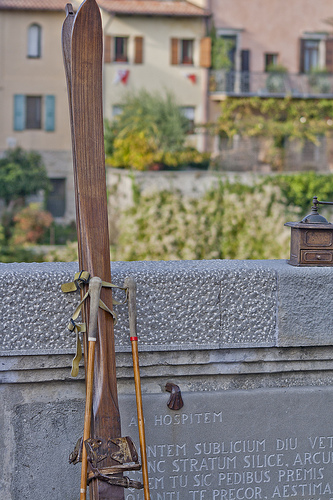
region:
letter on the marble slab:
[211, 409, 224, 426]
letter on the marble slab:
[202, 409, 212, 426]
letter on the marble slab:
[181, 412, 187, 424]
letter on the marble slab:
[154, 414, 160, 429]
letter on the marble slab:
[176, 441, 189, 458]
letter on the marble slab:
[193, 440, 202, 454]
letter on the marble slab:
[203, 442, 210, 455]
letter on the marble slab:
[210, 439, 219, 456]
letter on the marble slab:
[232, 438, 244, 453]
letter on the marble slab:
[255, 436, 270, 454]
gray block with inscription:
[5, 262, 330, 497]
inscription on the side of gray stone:
[111, 411, 331, 493]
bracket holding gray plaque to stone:
[157, 386, 184, 409]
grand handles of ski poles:
[87, 278, 135, 332]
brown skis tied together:
[54, 6, 131, 490]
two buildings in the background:
[2, 6, 332, 168]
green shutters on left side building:
[8, 92, 54, 131]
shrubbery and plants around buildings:
[2, 100, 319, 256]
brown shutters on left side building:
[104, 30, 212, 68]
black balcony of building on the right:
[212, 65, 329, 102]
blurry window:
[180, 36, 195, 65]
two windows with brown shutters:
[101, 34, 210, 67]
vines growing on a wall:
[103, 170, 331, 260]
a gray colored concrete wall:
[105, 168, 330, 260]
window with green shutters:
[12, 92, 54, 131]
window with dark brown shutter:
[299, 31, 331, 75]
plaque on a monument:
[117, 395, 328, 498]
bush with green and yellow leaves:
[104, 84, 211, 165]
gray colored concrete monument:
[0, 262, 332, 497]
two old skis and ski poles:
[62, 0, 149, 498]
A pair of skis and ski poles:
[57, 0, 152, 499]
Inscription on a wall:
[153, 412, 331, 498]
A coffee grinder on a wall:
[280, 187, 332, 280]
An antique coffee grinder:
[279, 195, 332, 270]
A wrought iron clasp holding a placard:
[157, 382, 198, 414]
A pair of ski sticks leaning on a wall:
[68, 270, 158, 498]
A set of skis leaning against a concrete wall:
[58, 0, 155, 499]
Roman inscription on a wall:
[155, 412, 332, 499]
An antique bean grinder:
[277, 188, 332, 269]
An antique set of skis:
[50, 0, 157, 499]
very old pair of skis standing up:
[57, 0, 140, 498]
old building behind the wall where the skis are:
[0, 1, 202, 246]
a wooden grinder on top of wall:
[285, 196, 331, 266]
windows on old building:
[104, 33, 199, 71]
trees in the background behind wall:
[107, 91, 205, 169]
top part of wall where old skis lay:
[1, 260, 331, 354]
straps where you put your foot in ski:
[70, 435, 140, 485]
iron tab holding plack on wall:
[163, 383, 185, 410]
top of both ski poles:
[84, 276, 142, 343]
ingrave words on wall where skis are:
[131, 432, 330, 498]